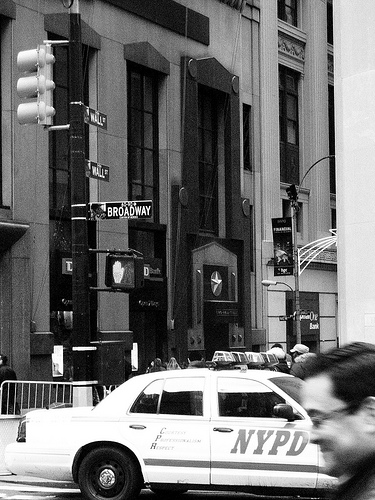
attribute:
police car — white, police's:
[4, 347, 338, 497]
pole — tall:
[53, 4, 100, 415]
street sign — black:
[87, 191, 155, 225]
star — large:
[207, 263, 228, 302]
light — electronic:
[98, 245, 142, 294]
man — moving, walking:
[287, 339, 375, 498]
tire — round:
[78, 447, 138, 499]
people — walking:
[137, 350, 179, 377]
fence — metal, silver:
[1, 373, 72, 417]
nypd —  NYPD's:
[229, 422, 310, 461]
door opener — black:
[210, 421, 234, 434]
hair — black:
[287, 339, 375, 416]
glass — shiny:
[217, 375, 283, 417]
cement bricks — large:
[0, 0, 254, 332]